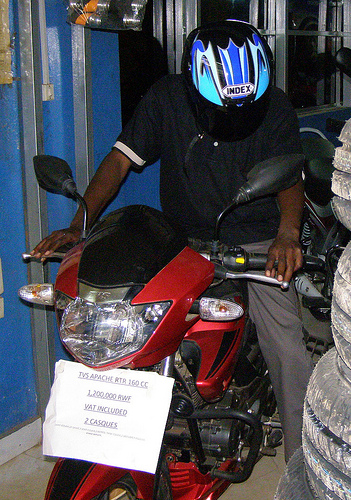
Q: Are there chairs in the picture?
A: No, there are no chairs.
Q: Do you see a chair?
A: No, there are no chairs.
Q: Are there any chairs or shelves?
A: No, there are no chairs or shelves.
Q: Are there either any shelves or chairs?
A: No, there are no chairs or shelves.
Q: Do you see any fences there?
A: No, there are no fences.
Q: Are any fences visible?
A: No, there are no fences.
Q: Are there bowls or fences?
A: No, there are no fences or bowls.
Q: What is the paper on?
A: The paper is on the motorcycle.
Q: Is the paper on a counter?
A: No, the paper is on a motorcycle.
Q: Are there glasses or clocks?
A: No, there are no glasses or clocks.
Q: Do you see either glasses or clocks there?
A: No, there are no glasses or clocks.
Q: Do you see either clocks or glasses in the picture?
A: No, there are no glasses or clocks.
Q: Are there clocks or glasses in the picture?
A: No, there are no glasses or clocks.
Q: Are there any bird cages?
A: No, there are no bird cages.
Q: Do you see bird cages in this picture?
A: No, there are no bird cages.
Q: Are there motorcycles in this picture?
A: Yes, there is a motorcycle.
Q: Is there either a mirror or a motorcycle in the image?
A: Yes, there is a motorcycle.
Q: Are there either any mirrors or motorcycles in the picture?
A: Yes, there is a motorcycle.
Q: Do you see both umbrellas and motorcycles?
A: No, there is a motorcycle but no umbrellas.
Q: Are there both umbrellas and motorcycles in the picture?
A: No, there is a motorcycle but no umbrellas.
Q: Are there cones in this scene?
A: No, there are no cones.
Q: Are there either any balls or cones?
A: No, there are no cones or balls.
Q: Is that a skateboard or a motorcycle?
A: That is a motorcycle.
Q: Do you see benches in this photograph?
A: No, there are no benches.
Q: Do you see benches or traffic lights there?
A: No, there are no benches or traffic lights.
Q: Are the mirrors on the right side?
A: Yes, the mirrors are on the right of the image.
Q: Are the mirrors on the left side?
A: No, the mirrors are on the right of the image.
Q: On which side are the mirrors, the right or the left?
A: The mirrors are on the right of the image.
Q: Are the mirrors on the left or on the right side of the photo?
A: The mirrors are on the right of the image.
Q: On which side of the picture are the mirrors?
A: The mirrors are on the right of the image.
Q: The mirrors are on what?
A: The mirrors are on the motorbike.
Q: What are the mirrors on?
A: The mirrors are on the motorbike.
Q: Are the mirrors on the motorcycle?
A: Yes, the mirrors are on the motorcycle.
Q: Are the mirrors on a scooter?
A: No, the mirrors are on the motorcycle.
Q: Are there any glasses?
A: No, there are no glasses.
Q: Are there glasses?
A: No, there are no glasses.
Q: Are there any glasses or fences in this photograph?
A: No, there are no glasses or fences.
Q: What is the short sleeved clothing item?
A: The clothing item is a shirt.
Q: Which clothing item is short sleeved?
A: The clothing item is a shirt.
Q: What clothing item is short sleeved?
A: The clothing item is a shirt.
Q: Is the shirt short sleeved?
A: Yes, the shirt is short sleeved.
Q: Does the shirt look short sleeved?
A: Yes, the shirt is short sleeved.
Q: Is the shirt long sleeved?
A: No, the shirt is short sleeved.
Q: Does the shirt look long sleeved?
A: No, the shirt is short sleeved.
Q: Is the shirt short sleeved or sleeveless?
A: The shirt is short sleeved.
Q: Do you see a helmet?
A: Yes, there is a helmet.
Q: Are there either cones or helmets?
A: Yes, there is a helmet.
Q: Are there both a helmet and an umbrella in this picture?
A: No, there is a helmet but no umbrellas.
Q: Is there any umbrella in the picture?
A: No, there are no umbrellas.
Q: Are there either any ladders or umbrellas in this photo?
A: No, there are no umbrellas or ladders.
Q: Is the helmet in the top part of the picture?
A: Yes, the helmet is in the top of the image.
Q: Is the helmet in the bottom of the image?
A: No, the helmet is in the top of the image.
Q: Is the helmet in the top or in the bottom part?
A: The helmet is in the top of the image.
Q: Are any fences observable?
A: No, there are no fences.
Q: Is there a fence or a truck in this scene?
A: No, there are no fences or trucks.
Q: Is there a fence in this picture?
A: No, there are no fences.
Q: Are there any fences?
A: No, there are no fences.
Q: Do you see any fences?
A: No, there are no fences.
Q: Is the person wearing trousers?
A: Yes, the person is wearing trousers.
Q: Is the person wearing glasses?
A: No, the person is wearing trousers.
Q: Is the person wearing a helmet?
A: Yes, the person is wearing a helmet.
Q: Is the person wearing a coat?
A: No, the person is wearing a helmet.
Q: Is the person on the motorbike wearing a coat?
A: No, the person is wearing a helmet.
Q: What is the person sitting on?
A: The person is sitting on the motorcycle.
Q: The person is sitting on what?
A: The person is sitting on the motorcycle.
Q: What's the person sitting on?
A: The person is sitting on the motorcycle.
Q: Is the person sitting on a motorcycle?
A: Yes, the person is sitting on a motorcycle.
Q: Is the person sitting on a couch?
A: No, the person is sitting on a motorcycle.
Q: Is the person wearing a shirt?
A: Yes, the person is wearing a shirt.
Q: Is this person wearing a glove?
A: No, the person is wearing a shirt.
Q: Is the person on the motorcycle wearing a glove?
A: No, the person is wearing a shirt.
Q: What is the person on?
A: The person is on the motorcycle.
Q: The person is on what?
A: The person is on the motorcycle.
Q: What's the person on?
A: The person is on the motorcycle.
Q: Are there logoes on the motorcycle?
A: No, there is a person on the motorcycle.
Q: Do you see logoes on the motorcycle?
A: No, there is a person on the motorcycle.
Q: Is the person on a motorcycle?
A: Yes, the person is on a motorcycle.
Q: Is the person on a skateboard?
A: No, the person is on a motorcycle.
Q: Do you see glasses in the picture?
A: No, there are no glasses.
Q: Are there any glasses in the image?
A: No, there are no glasses.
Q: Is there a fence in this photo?
A: No, there are no fences.